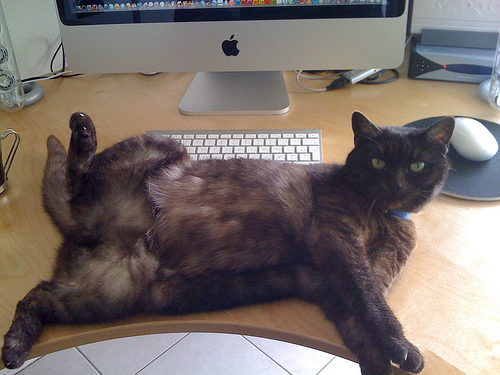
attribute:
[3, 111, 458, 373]
cat — laying, brown, black, twisted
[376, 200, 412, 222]
collar — blue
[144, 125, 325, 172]
keybaord — white, wireless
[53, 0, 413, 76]
computer — white